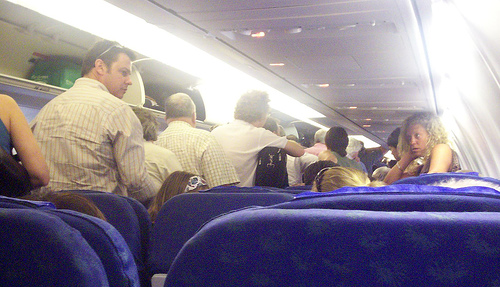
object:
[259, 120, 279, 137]
person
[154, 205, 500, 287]
seat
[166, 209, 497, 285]
seat back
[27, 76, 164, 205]
shirt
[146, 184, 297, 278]
seats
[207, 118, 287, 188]
white shirt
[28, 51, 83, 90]
luggage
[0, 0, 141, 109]
compartment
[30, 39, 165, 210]
man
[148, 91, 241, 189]
passenger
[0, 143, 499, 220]
aisle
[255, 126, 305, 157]
arm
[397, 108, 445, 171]
hair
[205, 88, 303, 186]
man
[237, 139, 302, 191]
luggage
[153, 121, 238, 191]
shirt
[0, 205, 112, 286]
saet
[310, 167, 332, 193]
headband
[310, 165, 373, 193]
head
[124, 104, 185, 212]
people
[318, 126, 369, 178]
people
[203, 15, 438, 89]
storage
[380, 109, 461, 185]
woman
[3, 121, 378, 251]
isle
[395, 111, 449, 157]
head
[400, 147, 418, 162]
hand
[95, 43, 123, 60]
sunglasses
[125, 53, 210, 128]
compartments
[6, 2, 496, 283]
airliner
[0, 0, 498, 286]
aircraft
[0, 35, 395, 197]
line